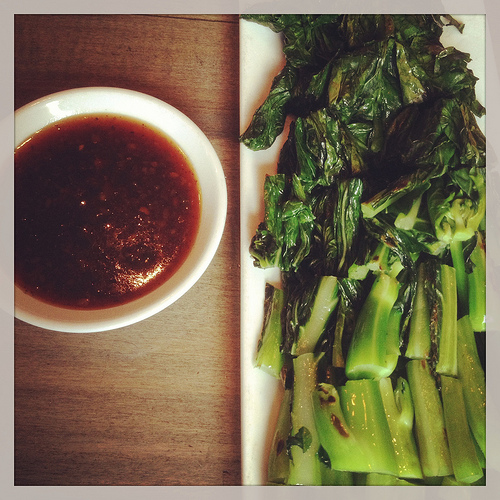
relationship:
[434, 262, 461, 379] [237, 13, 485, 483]
vegetable lying on top of plate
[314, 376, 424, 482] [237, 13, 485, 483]
vegetable on plate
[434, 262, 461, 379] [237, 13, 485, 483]
vegetable on plate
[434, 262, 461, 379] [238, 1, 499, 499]
vegetable on plate